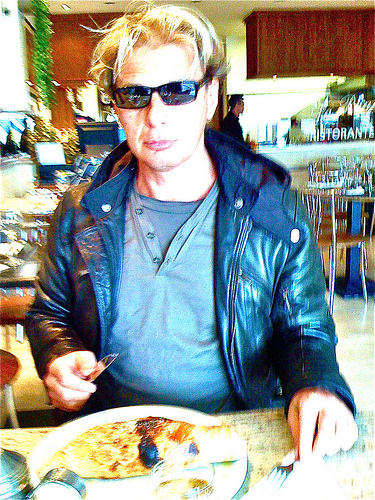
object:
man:
[25, 0, 359, 468]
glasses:
[109, 76, 213, 110]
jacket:
[25, 127, 356, 418]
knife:
[86, 351, 121, 384]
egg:
[37, 415, 242, 484]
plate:
[27, 403, 248, 499]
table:
[0, 408, 374, 498]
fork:
[266, 456, 300, 489]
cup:
[149, 455, 215, 499]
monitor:
[33, 142, 76, 167]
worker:
[216, 93, 256, 151]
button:
[135, 207, 144, 215]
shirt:
[103, 169, 233, 414]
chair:
[300, 186, 370, 315]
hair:
[78, 0, 231, 106]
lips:
[141, 139, 177, 150]